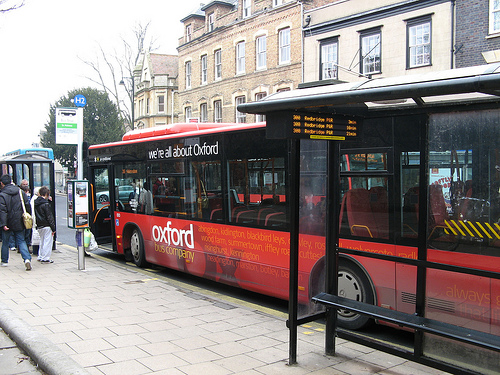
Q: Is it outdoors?
A: Yes, it is outdoors.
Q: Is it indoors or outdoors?
A: It is outdoors.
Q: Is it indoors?
A: No, it is outdoors.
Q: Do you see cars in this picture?
A: No, there are no cars.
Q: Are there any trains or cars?
A: No, there are no cars or trains.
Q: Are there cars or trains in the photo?
A: No, there are no cars or trains.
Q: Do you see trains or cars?
A: No, there are no cars or trains.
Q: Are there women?
A: Yes, there is a woman.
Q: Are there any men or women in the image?
A: Yes, there is a woman.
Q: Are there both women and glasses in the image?
A: No, there is a woman but no glasses.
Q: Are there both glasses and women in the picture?
A: No, there is a woman but no glasses.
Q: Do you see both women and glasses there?
A: No, there is a woman but no glasses.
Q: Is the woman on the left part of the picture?
A: Yes, the woman is on the left of the image.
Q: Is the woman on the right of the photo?
A: No, the woman is on the left of the image.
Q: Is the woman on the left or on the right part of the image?
A: The woman is on the left of the image.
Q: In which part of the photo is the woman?
A: The woman is on the left of the image.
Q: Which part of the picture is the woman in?
A: The woman is on the left of the image.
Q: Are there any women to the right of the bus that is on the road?
A: No, the woman is to the left of the bus.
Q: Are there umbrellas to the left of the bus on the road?
A: No, there is a woman to the left of the bus.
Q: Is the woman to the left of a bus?
A: Yes, the woman is to the left of a bus.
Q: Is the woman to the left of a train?
A: No, the woman is to the left of a bus.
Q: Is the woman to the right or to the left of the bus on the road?
A: The woman is to the left of the bus.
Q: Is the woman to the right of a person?
A: Yes, the woman is to the right of a person.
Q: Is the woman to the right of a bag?
A: No, the woman is to the right of a person.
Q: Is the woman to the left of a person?
A: No, the woman is to the right of a person.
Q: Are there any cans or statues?
A: No, there are no cans or statues.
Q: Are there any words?
A: Yes, there are words.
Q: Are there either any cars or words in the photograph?
A: Yes, there are words.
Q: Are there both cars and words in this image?
A: No, there are words but no cars.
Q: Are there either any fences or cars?
A: No, there are no fences or cars.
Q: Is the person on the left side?
A: Yes, the person is on the left of the image.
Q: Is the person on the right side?
A: No, the person is on the left of the image.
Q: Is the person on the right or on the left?
A: The person is on the left of the image.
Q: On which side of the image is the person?
A: The person is on the left of the image.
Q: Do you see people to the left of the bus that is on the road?
A: Yes, there is a person to the left of the bus.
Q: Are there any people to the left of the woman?
A: Yes, there is a person to the left of the woman.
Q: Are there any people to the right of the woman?
A: No, the person is to the left of the woman.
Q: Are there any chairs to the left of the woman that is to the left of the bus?
A: No, there is a person to the left of the woman.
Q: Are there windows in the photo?
A: Yes, there are windows.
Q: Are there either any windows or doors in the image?
A: Yes, there are windows.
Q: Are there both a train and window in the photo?
A: No, there are windows but no trains.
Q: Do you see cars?
A: No, there are no cars.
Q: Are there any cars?
A: No, there are no cars.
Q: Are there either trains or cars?
A: No, there are no cars or trains.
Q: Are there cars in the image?
A: No, there are no cars.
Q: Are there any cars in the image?
A: No, there are no cars.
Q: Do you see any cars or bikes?
A: No, there are no cars or bikes.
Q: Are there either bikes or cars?
A: No, there are no cars or bikes.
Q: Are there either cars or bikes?
A: No, there are no cars or bikes.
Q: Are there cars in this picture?
A: No, there are no cars.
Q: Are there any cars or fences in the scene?
A: No, there are no cars or fences.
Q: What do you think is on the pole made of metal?
A: The sign is on the pole.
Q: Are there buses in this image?
A: Yes, there is a bus.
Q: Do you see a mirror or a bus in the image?
A: Yes, there is a bus.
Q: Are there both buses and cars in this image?
A: No, there is a bus but no cars.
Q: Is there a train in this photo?
A: No, there are no trains.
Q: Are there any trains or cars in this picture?
A: No, there are no trains or cars.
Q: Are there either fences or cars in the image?
A: No, there are no fences or cars.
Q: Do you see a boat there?
A: No, there are no boats.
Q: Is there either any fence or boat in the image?
A: No, there are no boats or fences.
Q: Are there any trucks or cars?
A: No, there are no cars or trucks.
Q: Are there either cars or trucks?
A: No, there are no cars or trucks.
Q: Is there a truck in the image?
A: No, there are no trucks.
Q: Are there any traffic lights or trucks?
A: No, there are no trucks or traffic lights.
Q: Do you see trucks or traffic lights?
A: No, there are no trucks or traffic lights.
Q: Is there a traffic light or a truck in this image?
A: No, there are no trucks or traffic lights.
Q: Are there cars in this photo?
A: No, there are no cars.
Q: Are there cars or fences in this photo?
A: No, there are no cars or fences.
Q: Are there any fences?
A: No, there are no fences.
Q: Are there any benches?
A: Yes, there is a bench.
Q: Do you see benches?
A: Yes, there is a bench.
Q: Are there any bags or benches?
A: Yes, there is a bench.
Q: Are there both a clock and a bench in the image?
A: No, there is a bench but no clocks.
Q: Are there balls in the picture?
A: No, there are no balls.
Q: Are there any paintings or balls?
A: No, there are no balls or paintings.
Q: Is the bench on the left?
A: No, the bench is on the right of the image.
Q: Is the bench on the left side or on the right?
A: The bench is on the right of the image.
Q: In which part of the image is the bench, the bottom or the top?
A: The bench is in the bottom of the image.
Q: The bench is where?
A: The bench is at the bus stop.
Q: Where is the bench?
A: The bench is at the bus stop.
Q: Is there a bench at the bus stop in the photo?
A: Yes, there is a bench at the bus stop.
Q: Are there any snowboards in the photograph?
A: No, there are no snowboards.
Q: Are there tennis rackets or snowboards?
A: No, there are no snowboards or tennis rackets.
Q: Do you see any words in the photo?
A: Yes, there are words.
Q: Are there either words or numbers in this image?
A: Yes, there are words.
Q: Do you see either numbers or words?
A: Yes, there are words.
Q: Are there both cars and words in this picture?
A: No, there are words but no cars.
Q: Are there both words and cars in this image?
A: No, there are words but no cars.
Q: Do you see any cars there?
A: No, there are no cars.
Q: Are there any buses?
A: Yes, there is a bus.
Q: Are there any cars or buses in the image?
A: Yes, there is a bus.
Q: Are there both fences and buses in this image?
A: No, there is a bus but no fences.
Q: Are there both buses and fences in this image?
A: No, there is a bus but no fences.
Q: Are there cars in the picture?
A: No, there are no cars.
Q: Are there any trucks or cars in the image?
A: No, there are no cars or trucks.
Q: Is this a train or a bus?
A: This is a bus.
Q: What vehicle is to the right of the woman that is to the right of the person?
A: The vehicle is a bus.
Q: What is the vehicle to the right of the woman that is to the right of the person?
A: The vehicle is a bus.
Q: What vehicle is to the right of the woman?
A: The vehicle is a bus.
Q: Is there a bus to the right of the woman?
A: Yes, there is a bus to the right of the woman.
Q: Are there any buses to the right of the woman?
A: Yes, there is a bus to the right of the woman.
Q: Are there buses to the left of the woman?
A: No, the bus is to the right of the woman.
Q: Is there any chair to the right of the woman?
A: No, there is a bus to the right of the woman.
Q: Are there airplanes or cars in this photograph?
A: No, there are no cars or airplanes.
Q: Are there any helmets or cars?
A: No, there are no cars or helmets.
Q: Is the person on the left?
A: Yes, the person is on the left of the image.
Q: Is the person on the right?
A: No, the person is on the left of the image.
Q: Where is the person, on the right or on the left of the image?
A: The person is on the left of the image.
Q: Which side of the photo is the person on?
A: The person is on the left of the image.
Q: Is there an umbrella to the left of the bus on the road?
A: No, there is a person to the left of the bus.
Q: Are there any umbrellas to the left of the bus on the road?
A: No, there is a person to the left of the bus.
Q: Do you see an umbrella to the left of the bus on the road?
A: No, there is a person to the left of the bus.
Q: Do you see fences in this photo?
A: No, there are no fences.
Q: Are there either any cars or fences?
A: No, there are no fences or cars.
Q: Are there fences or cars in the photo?
A: No, there are no fences or cars.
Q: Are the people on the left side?
A: Yes, the people are on the left of the image.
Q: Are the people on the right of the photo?
A: No, the people are on the left of the image.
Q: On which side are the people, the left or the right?
A: The people are on the left of the image.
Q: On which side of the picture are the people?
A: The people are on the left of the image.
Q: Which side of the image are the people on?
A: The people are on the left of the image.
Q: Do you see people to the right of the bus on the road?
A: No, the people are to the left of the bus.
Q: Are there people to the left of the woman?
A: Yes, there are people to the left of the woman.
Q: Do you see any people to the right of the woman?
A: No, the people are to the left of the woman.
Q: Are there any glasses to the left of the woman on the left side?
A: No, there are people to the left of the woman.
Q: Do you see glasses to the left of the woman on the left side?
A: No, there are people to the left of the woman.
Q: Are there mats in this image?
A: No, there are no mats.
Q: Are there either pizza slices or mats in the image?
A: No, there are no mats or pizza slices.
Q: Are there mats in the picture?
A: No, there are no mats.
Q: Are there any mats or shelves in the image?
A: No, there are no mats or shelves.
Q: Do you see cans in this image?
A: No, there are no cans.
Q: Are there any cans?
A: No, there are no cans.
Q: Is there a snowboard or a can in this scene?
A: No, there are no cans or snowboards.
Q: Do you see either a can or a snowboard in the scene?
A: No, there are no cans or snowboards.